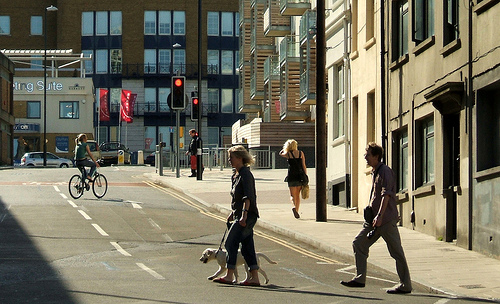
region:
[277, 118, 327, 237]
Blonde woman with black dress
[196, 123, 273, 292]
Woman leading white dog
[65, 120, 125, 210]
Woman with blue shirt riding bike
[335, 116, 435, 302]
Man walking across the street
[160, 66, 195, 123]
Traffic light showing red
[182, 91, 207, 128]
Traffic light showing red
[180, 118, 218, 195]
Man standing by the side of the road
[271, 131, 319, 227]
Woman walking down the street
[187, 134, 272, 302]
Woman crossing street with dog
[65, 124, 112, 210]
Woman riding a bike across the street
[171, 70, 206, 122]
two red stoplights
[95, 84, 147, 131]
two red flags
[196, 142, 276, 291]
a woman walking her dog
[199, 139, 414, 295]
two people crossing the street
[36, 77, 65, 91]
The word Suite in silver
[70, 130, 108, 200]
a girl riding a bike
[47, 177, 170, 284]
white dotted lines on the road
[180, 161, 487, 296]
a sidewalk that goes up hill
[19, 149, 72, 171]
a silver four door car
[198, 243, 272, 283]
a short haired dog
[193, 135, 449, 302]
People crossing a street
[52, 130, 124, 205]
a woman riding a bike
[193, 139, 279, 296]
A woman walking a white dog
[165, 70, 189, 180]
A red traffic light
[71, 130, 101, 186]
A woman wearing a ponytail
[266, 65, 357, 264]
A woman walking up a hill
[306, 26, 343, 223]
a brown pole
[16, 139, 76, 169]
a gray car on the road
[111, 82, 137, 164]
A red and white flag on a pole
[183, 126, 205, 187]
A man wearing a black jacket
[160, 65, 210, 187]
two traffic lights for traffic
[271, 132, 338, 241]
lady walking on side walk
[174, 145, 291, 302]
lady crossing street with dog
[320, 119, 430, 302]
man crossing street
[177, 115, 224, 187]
man standing at traffic light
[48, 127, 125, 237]
lady on bicycle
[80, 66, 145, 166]
two red flags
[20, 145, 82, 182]
silver car parked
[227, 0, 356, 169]
apartment building on side of road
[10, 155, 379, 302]
tar covered road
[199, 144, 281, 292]
a woman with a dog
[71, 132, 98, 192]
a woman on a bike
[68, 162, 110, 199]
a bicycle on the street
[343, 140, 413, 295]
a man crossing the street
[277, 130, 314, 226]
a blonde woman in a dress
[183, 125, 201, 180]
a person in red pants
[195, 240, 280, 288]
a white dog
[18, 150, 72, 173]
a silver van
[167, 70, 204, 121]
two traffic lights